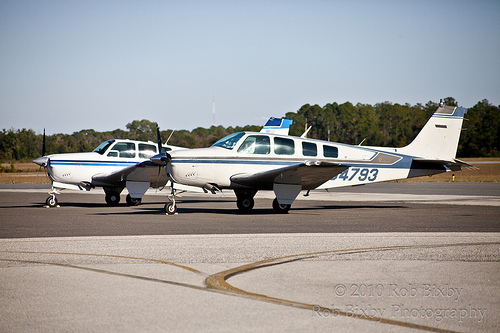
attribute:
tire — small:
[164, 201, 178, 215]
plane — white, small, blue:
[147, 105, 471, 215]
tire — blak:
[125, 191, 142, 204]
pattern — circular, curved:
[206, 240, 496, 332]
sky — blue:
[3, 1, 498, 126]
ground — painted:
[1, 183, 498, 330]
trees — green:
[1, 101, 498, 157]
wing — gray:
[92, 159, 166, 182]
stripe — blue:
[169, 156, 372, 161]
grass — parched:
[1, 160, 498, 184]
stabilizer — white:
[414, 105, 466, 159]